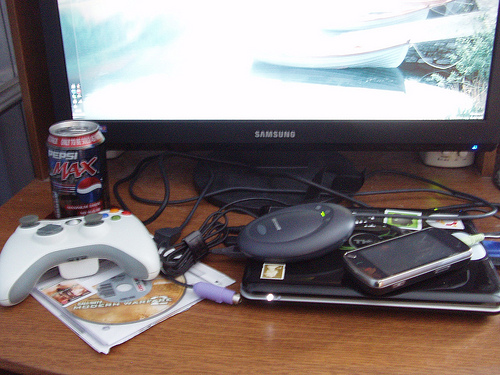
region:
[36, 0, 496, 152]
Samsung computer is on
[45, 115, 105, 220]
Pepsi Max soda can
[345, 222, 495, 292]
a plugged in cellphone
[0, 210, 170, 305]
a white video came controller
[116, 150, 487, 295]
multiple wires on table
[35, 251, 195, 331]
a video game CD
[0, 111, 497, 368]
a light brown table with electronics on top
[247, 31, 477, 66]
a boat tied to a dock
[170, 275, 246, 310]
an unplugged cord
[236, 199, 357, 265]
a grey mouse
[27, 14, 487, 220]
computer monitor on desk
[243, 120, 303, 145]
name of electronics company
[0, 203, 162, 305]
white game controller with buttons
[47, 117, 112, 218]
can of soft drink on desk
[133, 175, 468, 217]
black wires across desk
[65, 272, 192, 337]
disk in plastic case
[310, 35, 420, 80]
boat on computer screen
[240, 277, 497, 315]
edge of closed laptop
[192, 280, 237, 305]
purple plastic on cable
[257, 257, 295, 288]
sticker on laptop cover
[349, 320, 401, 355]
part of a desktop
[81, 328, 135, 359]
edge of a case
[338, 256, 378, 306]
edge of a phone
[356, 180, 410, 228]
part of some wires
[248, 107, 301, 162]
edge of a monitor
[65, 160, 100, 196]
side of a can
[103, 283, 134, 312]
top of a compact disc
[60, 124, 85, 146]
top of a can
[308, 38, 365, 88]
screen of a monitor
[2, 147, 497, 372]
desk with brown wood-like appearance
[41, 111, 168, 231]
aluminum soft drink container on desk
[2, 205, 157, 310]
white and grey game controller with redo, orange, blue and green buttons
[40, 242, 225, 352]
disks on desktop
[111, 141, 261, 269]
black cords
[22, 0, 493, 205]
large monitor on desk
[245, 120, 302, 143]
brand of monitor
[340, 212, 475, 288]
cellular phone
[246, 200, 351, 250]
green light on device is lit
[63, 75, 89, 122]
small icons on monitor display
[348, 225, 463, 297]
this is a phone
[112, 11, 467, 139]
this is a television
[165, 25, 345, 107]
the television is on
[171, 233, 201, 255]
this is a cable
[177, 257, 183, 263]
the cable is black in color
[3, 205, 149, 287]
this is a pad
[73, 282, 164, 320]
this is a compact disc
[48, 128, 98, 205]
this is a container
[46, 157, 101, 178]
the container is written max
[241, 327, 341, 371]
this is a table